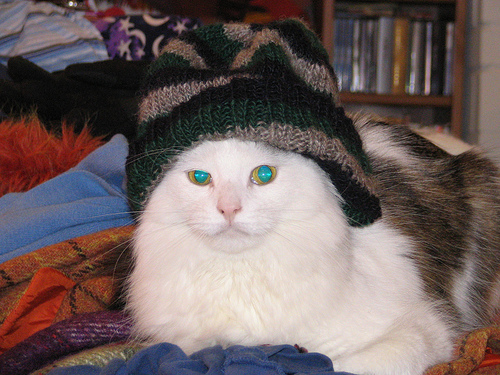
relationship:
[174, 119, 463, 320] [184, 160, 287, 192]
cat has eye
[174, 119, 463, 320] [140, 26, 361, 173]
cat wearing hat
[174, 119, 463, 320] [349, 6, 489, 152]
cat near bookcase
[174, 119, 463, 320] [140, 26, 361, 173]
cat has hat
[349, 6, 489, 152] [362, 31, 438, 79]
bookcase has books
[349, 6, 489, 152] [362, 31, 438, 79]
bookcase holding books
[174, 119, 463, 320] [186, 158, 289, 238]
cat has eyes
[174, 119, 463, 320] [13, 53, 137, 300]
cat on bed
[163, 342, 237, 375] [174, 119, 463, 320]
blankets under cat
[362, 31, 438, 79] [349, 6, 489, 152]
books on bookcase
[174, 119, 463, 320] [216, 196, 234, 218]
cat has nose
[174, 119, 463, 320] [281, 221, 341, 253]
cat has wiskers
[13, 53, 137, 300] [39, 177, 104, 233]
bed has clothing